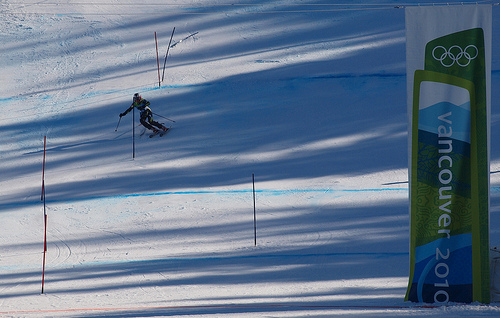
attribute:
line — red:
[5, 288, 293, 316]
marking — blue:
[76, 161, 347, 206]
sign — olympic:
[430, 41, 483, 73]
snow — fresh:
[273, 165, 363, 228]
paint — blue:
[62, 172, 412, 204]